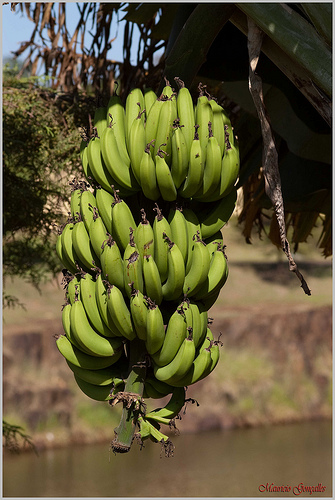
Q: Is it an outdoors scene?
A: Yes, it is outdoors.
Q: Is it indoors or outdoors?
A: It is outdoors.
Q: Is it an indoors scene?
A: No, it is outdoors.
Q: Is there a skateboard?
A: No, there are no skateboards.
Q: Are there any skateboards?
A: No, there are no skateboards.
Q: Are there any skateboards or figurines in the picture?
A: No, there are no skateboards or figurines.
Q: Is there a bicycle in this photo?
A: No, there are no bicycles.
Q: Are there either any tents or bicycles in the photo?
A: No, there are no bicycles or tents.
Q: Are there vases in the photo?
A: No, there are no vases.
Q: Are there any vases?
A: No, there are no vases.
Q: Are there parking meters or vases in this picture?
A: No, there are no vases or parking meters.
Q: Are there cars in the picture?
A: No, there are no cars.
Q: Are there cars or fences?
A: No, there are no cars or fences.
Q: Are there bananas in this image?
A: Yes, there is a banana.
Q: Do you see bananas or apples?
A: Yes, there is a banana.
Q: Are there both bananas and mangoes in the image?
A: No, there is a banana but no mangoes.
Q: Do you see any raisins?
A: No, there are no raisins.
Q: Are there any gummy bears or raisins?
A: No, there are no raisins or gummy bears.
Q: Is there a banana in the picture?
A: Yes, there is a banana.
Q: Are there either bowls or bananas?
A: Yes, there is a banana.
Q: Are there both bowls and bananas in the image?
A: No, there is a banana but no bowls.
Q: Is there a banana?
A: Yes, there is a banana.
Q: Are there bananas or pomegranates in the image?
A: Yes, there is a banana.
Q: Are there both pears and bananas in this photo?
A: No, there is a banana but no pears.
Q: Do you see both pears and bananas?
A: No, there is a banana but no pears.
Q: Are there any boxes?
A: No, there are no boxes.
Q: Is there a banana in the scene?
A: Yes, there is a banana.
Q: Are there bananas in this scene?
A: Yes, there is a banana.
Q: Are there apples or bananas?
A: Yes, there is a banana.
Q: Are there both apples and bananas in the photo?
A: No, there is a banana but no apples.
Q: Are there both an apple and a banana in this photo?
A: No, there is a banana but no apples.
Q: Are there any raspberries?
A: No, there are no raspberries.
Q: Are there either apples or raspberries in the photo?
A: No, there are no raspberries or apples.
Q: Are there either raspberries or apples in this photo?
A: No, there are no raspberries or apples.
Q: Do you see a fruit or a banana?
A: Yes, there is a banana.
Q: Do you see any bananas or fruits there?
A: Yes, there is a banana.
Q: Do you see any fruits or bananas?
A: Yes, there is a banana.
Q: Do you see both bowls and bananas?
A: No, there is a banana but no bowls.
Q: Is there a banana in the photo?
A: Yes, there is a banana.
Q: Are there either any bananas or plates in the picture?
A: Yes, there is a banana.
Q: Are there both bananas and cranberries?
A: No, there is a banana but no cranberries.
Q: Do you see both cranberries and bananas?
A: No, there is a banana but no cranberries.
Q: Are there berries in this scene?
A: No, there are no berries.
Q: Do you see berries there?
A: No, there are no berries.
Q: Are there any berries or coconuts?
A: No, there are no berries or coconuts.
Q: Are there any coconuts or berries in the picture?
A: No, there are no berries or coconuts.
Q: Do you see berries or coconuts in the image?
A: No, there are no berries or coconuts.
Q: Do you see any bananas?
A: Yes, there is a banana.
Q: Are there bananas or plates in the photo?
A: Yes, there is a banana.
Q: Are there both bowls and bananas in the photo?
A: No, there is a banana but no bowls.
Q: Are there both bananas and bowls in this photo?
A: No, there is a banana but no bowls.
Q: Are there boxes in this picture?
A: No, there are no boxes.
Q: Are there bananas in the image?
A: Yes, there is a banana.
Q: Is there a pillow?
A: No, there are no pillows.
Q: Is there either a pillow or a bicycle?
A: No, there are no pillows or bicycles.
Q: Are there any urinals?
A: No, there are no urinals.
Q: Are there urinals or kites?
A: No, there are no urinals or kites.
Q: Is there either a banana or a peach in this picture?
A: Yes, there is a banana.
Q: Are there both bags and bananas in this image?
A: No, there is a banana but no bags.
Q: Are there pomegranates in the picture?
A: No, there are no pomegranates.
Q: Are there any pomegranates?
A: No, there are no pomegranates.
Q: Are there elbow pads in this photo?
A: No, there are no elbow pads.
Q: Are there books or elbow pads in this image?
A: No, there are no elbow pads or books.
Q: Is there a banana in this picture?
A: Yes, there are bananas.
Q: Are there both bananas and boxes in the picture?
A: No, there are bananas but no boxes.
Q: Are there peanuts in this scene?
A: No, there are no peanuts.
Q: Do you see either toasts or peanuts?
A: No, there are no peanuts or toasts.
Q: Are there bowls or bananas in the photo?
A: Yes, there is a banana.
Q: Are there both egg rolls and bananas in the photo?
A: No, there is a banana but no egg rolls.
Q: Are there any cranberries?
A: No, there are no cranberries.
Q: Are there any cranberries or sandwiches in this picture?
A: No, there are no cranberries or sandwiches.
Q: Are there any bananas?
A: Yes, there is a banana.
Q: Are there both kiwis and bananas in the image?
A: No, there is a banana but no kiwis.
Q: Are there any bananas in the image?
A: Yes, there is a banana.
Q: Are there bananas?
A: Yes, there is a banana.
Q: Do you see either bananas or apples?
A: Yes, there is a banana.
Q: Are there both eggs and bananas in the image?
A: No, there is a banana but no eggs.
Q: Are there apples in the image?
A: No, there are no apples.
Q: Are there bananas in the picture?
A: Yes, there is a banana.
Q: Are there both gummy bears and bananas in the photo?
A: No, there is a banana but no gummy bears.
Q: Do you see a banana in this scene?
A: Yes, there is a banana.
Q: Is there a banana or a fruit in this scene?
A: Yes, there is a banana.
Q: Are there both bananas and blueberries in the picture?
A: No, there is a banana but no blueberries.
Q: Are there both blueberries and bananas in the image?
A: No, there is a banana but no blueberries.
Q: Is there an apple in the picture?
A: No, there are no apples.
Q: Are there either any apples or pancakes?
A: No, there are no apples or pancakes.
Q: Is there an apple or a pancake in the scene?
A: No, there are no apples or pancakes.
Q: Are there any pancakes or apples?
A: No, there are no apples or pancakes.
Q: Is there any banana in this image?
A: Yes, there is a banana.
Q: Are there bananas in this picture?
A: Yes, there is a banana.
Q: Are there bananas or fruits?
A: Yes, there is a banana.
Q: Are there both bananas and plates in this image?
A: No, there is a banana but no plates.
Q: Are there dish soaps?
A: No, there are no dish soaps.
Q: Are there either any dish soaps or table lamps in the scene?
A: No, there are no dish soaps or table lamps.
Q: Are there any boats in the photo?
A: No, there are no boats.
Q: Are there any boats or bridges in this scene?
A: No, there are no boats or bridges.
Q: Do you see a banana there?
A: Yes, there is a banana.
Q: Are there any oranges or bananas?
A: Yes, there is a banana.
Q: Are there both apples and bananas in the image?
A: No, there is a banana but no apples.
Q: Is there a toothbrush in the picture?
A: No, there are no toothbrushes.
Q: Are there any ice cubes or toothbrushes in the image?
A: No, there are no toothbrushes or ice cubes.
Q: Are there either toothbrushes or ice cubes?
A: No, there are no toothbrushes or ice cubes.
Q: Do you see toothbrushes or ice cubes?
A: No, there are no toothbrushes or ice cubes.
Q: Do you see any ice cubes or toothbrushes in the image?
A: No, there are no toothbrushes or ice cubes.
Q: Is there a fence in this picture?
A: No, there are no fences.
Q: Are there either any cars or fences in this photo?
A: No, there are no fences or cars.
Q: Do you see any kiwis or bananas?
A: Yes, there is a banana.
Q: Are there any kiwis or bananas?
A: Yes, there is a banana.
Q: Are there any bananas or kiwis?
A: Yes, there is a banana.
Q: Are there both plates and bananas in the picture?
A: No, there is a banana but no plates.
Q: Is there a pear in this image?
A: No, there are no pears.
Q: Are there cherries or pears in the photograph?
A: No, there are no pears or cherries.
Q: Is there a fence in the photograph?
A: No, there are no fences.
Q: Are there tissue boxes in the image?
A: No, there are no tissue boxes.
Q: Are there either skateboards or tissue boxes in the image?
A: No, there are no tissue boxes or skateboards.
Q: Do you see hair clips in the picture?
A: No, there are no hair clips.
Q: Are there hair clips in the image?
A: No, there are no hair clips.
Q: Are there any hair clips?
A: No, there are no hair clips.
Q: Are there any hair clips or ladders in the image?
A: No, there are no hair clips or ladders.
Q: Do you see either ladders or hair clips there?
A: No, there are no hair clips or ladders.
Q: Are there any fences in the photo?
A: No, there are no fences.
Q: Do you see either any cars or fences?
A: No, there are no fences or cars.